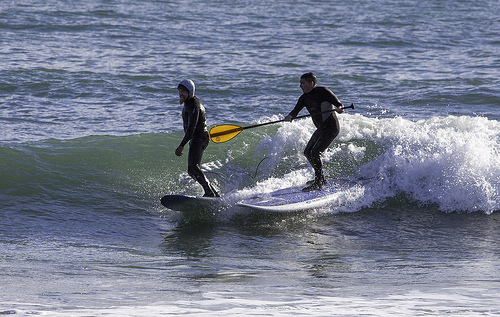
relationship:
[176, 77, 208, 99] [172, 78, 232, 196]
helmet on man